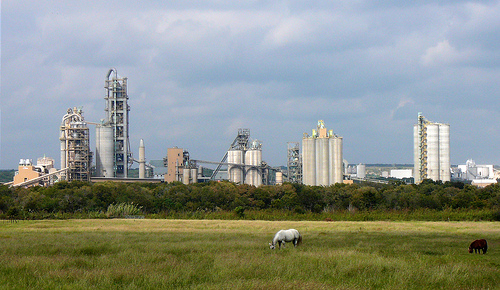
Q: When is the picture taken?
A: Daytime.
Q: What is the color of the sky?
A: Blue with clouds.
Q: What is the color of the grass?
A: Green.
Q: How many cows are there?
A: 2.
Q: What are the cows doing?
A: Eating.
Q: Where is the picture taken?
A: In a field.